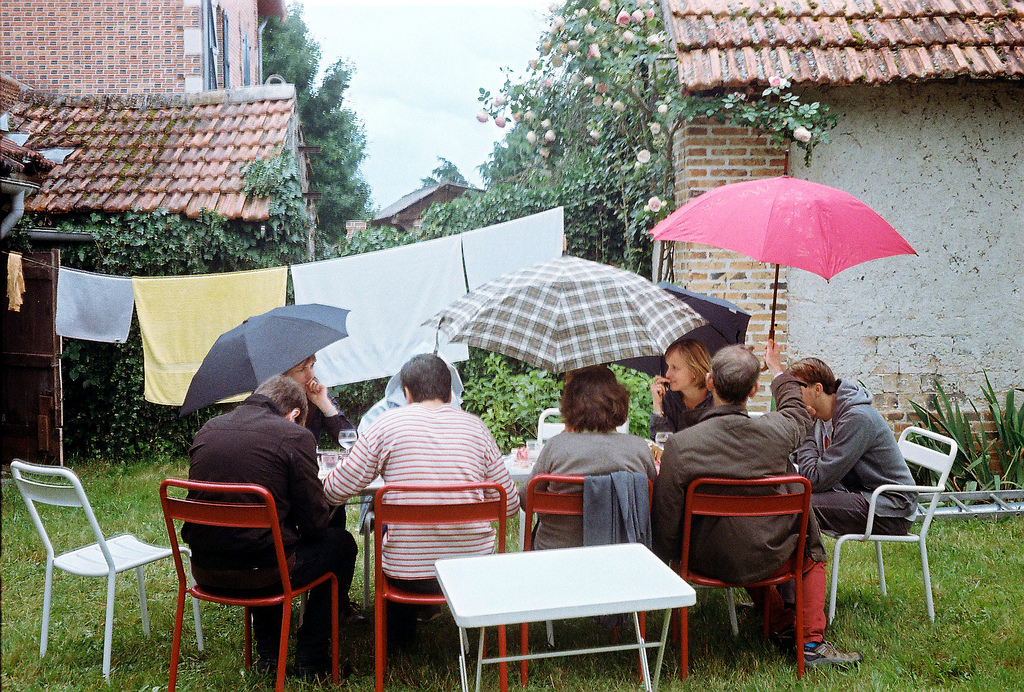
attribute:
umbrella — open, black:
[178, 283, 384, 417]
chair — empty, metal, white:
[5, 458, 192, 689]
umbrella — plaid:
[435, 251, 692, 381]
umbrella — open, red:
[645, 166, 892, 284]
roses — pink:
[475, 40, 773, 225]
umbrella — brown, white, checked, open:
[422, 247, 707, 371]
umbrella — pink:
[629, 169, 921, 339]